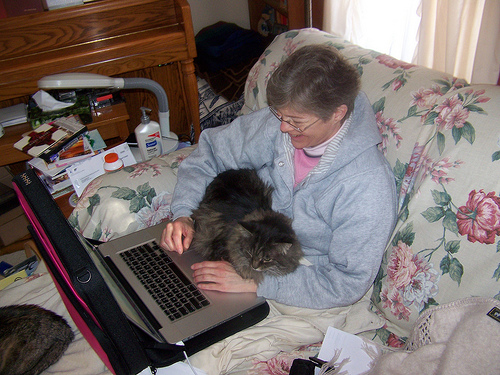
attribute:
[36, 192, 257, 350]
laptop — silver, black, grey, large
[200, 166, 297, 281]
cat — grey, sitting, gray, adult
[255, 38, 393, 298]
woman — sitting, happy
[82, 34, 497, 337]
sofa — floral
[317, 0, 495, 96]
window — white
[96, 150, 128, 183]
bottle — red, white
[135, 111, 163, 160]
bottle — large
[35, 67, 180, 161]
lamp — one, directional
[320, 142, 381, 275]
gray — grey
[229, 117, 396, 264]
shirt — hooded, grey, unisex, blue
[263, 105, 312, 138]
glasses — silver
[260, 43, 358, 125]
hair — grey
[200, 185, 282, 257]
hair — grey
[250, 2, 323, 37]
cupboard — brown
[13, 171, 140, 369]
case — pink, black